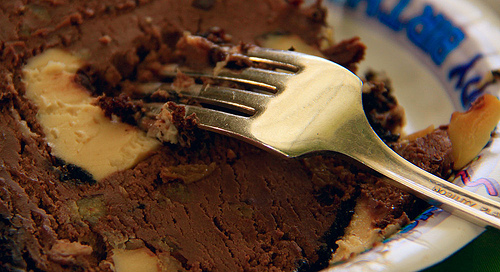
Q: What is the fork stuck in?
A: Ice cream.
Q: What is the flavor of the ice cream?
A: Chocolate.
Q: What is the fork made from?
A: Steel.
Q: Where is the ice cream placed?
A: In a plate.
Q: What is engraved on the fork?
A: Letters.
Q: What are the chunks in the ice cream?
A: Dried fruits.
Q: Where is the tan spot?
A: On the dessert.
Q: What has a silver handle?
A: Fork.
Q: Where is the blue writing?
A: On the paper plate.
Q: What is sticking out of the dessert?
A: Fork.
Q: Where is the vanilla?
A: On the frosting.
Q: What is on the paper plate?
A: Cake.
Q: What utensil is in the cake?
A: Fork.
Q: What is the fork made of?
A: Silver.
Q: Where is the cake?
A: On the fork.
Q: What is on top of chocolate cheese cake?
A: Fork.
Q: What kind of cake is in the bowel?
A: Chocolate cake.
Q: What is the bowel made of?
A: China.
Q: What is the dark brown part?
A: Chocolate.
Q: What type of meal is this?
A: Dessert.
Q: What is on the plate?
A: A cake.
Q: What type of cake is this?
A: A chocolate cake.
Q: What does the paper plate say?
A: Happy birthday.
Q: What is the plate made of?
A: Paper.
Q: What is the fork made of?
A: Silver metal.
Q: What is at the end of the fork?
A: Cake crumbs.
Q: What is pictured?
A: A piece of cake.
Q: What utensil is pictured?
A: A fork.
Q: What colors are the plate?
A: Blue and white.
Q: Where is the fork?
A: In the cake.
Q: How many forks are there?
A: One.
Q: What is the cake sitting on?
A: A plate.